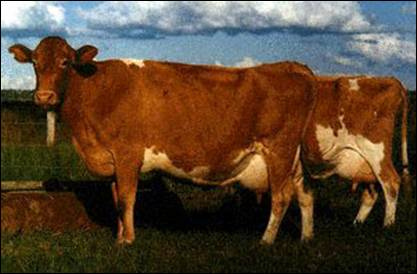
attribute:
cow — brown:
[292, 68, 414, 234]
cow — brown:
[9, 32, 316, 238]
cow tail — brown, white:
[397, 92, 414, 189]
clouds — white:
[0, 0, 365, 36]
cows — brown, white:
[251, 66, 410, 226]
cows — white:
[8, 34, 334, 246]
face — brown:
[7, 35, 100, 111]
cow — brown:
[31, 24, 315, 238]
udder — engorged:
[334, 146, 369, 182]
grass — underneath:
[136, 218, 258, 272]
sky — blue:
[34, 4, 406, 70]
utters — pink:
[345, 160, 387, 193]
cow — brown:
[15, 35, 296, 229]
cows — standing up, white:
[2, 29, 413, 250]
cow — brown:
[313, 65, 416, 225]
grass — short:
[36, 200, 114, 259]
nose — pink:
[20, 87, 63, 128]